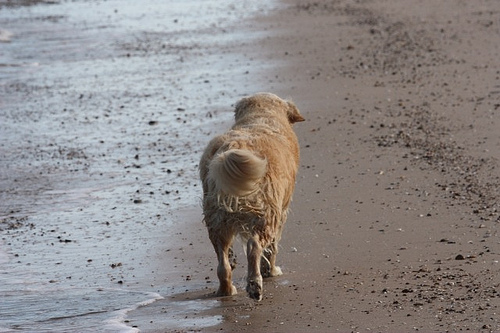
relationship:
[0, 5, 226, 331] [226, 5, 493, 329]
ocean water coming up beach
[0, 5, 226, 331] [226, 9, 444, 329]
ocean water coming up sand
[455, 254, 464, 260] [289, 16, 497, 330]
rock are in sand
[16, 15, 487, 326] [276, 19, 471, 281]
beach made of sand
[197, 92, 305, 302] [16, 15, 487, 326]
dog walking on beach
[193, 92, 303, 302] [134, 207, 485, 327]
dog walking on sand